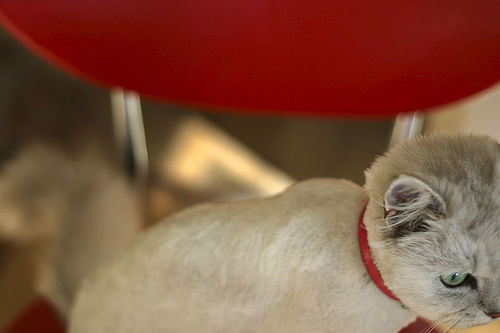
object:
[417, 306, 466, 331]
whiskers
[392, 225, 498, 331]
face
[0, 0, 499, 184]
table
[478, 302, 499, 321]
nose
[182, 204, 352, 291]
fur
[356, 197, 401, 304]
red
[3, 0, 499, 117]
chair back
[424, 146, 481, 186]
fur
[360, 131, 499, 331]
head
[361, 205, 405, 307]
collar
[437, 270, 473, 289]
eye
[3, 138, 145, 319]
tail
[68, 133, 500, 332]
cat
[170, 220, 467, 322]
highlights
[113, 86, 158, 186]
support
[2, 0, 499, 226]
chair